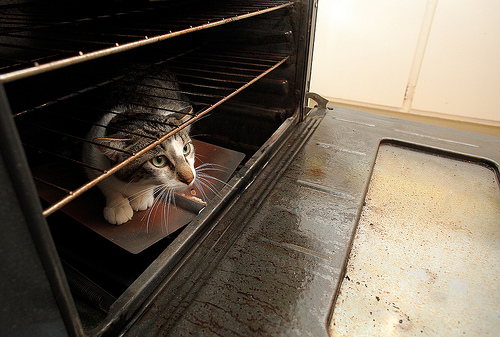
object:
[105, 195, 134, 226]
paw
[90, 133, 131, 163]
ear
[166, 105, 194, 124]
ear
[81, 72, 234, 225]
cat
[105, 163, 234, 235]
whiskers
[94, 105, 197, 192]
head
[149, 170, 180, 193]
jaw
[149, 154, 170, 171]
eye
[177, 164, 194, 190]
nose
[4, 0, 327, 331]
oven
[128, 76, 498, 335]
door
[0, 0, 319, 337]
window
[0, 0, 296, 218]
rack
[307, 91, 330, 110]
hinge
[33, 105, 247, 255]
plate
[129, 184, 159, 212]
paw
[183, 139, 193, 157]
eye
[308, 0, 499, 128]
wall